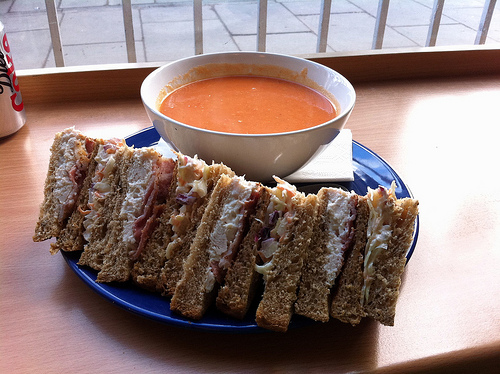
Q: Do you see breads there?
A: Yes, there is a bread.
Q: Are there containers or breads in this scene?
A: Yes, there is a bread.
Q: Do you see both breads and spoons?
A: No, there is a bread but no spoons.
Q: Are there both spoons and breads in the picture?
A: No, there is a bread but no spoons.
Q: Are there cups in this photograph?
A: No, there are no cups.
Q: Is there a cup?
A: No, there are no cups.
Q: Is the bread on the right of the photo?
A: Yes, the bread is on the right of the image.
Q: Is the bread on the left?
A: No, the bread is on the right of the image.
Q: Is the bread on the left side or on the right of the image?
A: The bread is on the right of the image.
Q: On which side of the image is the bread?
A: The bread is on the right of the image.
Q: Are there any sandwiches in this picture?
A: Yes, there is a sandwich.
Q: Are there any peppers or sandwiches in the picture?
A: Yes, there is a sandwich.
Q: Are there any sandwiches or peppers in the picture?
A: Yes, there is a sandwich.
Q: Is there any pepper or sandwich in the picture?
A: Yes, there is a sandwich.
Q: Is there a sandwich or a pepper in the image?
A: Yes, there is a sandwich.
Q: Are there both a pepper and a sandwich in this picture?
A: No, there is a sandwich but no peppers.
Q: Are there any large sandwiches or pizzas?
A: Yes, there is a large sandwich.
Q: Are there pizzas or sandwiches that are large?
A: Yes, the sandwich is large.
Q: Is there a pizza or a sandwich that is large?
A: Yes, the sandwich is large.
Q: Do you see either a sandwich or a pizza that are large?
A: Yes, the sandwich is large.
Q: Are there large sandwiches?
A: Yes, there is a large sandwich.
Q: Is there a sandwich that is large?
A: Yes, there is a sandwich that is large.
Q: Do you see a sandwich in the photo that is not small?
A: Yes, there is a large sandwich.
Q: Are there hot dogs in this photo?
A: No, there are no hot dogs.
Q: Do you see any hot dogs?
A: No, there are no hot dogs.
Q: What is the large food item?
A: The food item is a sandwich.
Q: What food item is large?
A: The food item is a sandwich.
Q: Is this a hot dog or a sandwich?
A: This is a sandwich.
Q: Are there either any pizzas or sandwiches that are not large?
A: No, there is a sandwich but it is large.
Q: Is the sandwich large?
A: Yes, the sandwich is large.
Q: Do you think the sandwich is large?
A: Yes, the sandwich is large.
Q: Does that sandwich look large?
A: Yes, the sandwich is large.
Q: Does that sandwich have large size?
A: Yes, the sandwich is large.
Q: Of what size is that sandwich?
A: The sandwich is large.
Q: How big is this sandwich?
A: The sandwich is large.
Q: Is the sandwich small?
A: No, the sandwich is large.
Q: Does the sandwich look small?
A: No, the sandwich is large.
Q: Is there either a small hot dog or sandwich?
A: No, there is a sandwich but it is large.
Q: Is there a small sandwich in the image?
A: No, there is a sandwich but it is large.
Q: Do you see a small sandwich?
A: No, there is a sandwich but it is large.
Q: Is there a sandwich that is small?
A: No, there is a sandwich but it is large.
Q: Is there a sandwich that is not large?
A: No, there is a sandwich but it is large.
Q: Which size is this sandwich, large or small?
A: The sandwich is large.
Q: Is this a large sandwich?
A: Yes, this is a large sandwich.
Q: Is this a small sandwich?
A: No, this is a large sandwich.